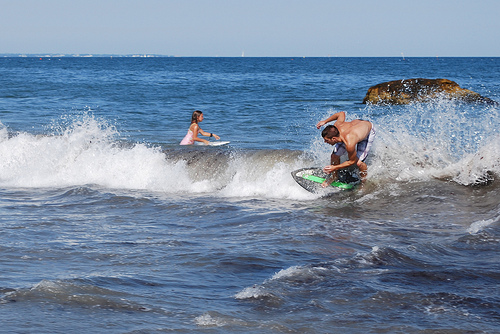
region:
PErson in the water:
[286, 88, 403, 261]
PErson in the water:
[171, 99, 221, 163]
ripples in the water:
[18, 261, 88, 315]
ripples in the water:
[78, 271, 113, 303]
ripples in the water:
[120, 273, 177, 333]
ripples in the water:
[178, 281, 243, 333]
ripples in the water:
[248, 254, 317, 311]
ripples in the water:
[209, 188, 271, 250]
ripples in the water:
[108, 169, 186, 227]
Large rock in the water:
[348, 60, 499, 135]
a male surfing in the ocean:
[303, 88, 386, 235]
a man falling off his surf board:
[302, 104, 402, 223]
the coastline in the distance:
[7, 46, 261, 88]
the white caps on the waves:
[8, 110, 176, 228]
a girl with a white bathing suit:
[183, 97, 233, 182]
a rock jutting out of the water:
[368, 70, 489, 122]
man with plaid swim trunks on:
[350, 114, 381, 189]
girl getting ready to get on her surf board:
[182, 93, 239, 175]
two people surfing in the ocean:
[162, 103, 412, 220]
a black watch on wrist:
[206, 108, 223, 172]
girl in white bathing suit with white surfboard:
[173, 105, 231, 157]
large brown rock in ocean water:
[365, 75, 488, 110]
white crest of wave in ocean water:
[3, 103, 498, 193]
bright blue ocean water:
[8, 55, 498, 317]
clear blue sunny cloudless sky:
[9, 2, 497, 55]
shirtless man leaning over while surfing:
[289, 104, 376, 191]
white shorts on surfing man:
[330, 142, 369, 177]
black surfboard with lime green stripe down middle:
[291, 163, 371, 194]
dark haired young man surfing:
[292, 105, 381, 203]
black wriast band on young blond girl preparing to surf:
[209, 131, 219, 139]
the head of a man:
[319, 119, 356, 144]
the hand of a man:
[308, 110, 329, 128]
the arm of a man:
[322, 128, 377, 189]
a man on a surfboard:
[264, 87, 408, 223]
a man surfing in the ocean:
[267, 89, 405, 230]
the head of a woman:
[189, 104, 208, 132]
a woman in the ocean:
[167, 83, 246, 155]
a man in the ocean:
[286, 85, 396, 215]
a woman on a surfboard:
[164, 97, 268, 154]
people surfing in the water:
[70, 79, 453, 242]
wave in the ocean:
[153, 177, 168, 192]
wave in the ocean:
[258, 181, 270, 191]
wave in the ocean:
[401, 158, 421, 178]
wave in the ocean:
[74, 217, 91, 232]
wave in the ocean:
[276, 294, 296, 306]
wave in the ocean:
[268, 119, 292, 136]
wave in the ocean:
[366, 285, 394, 307]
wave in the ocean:
[277, 268, 297, 280]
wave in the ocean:
[106, 227, 125, 245]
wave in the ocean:
[247, 283, 285, 304]